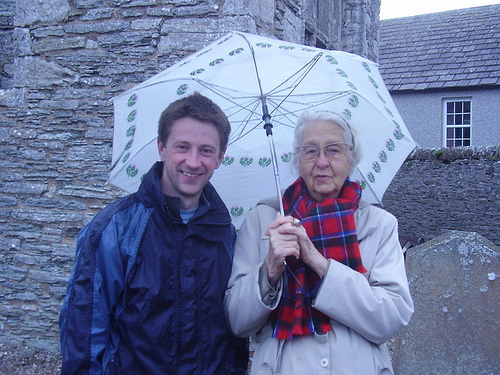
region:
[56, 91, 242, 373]
man under an umbrella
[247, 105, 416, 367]
woman under an umbrella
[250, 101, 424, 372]
woman next to man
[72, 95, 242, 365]
man next to woman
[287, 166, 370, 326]
scarf around woman's neck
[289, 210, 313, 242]
ring on woman's finger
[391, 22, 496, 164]
house in the background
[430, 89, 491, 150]
window on the house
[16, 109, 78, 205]
stones on a building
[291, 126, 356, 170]
glasses on the woman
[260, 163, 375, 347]
this is a red scarf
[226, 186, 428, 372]
this is a tan jacket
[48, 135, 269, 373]
this is a jacket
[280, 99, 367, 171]
this is white hair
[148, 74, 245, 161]
this is brown hair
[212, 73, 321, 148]
this is an umbrella frame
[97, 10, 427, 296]
this is an umbrella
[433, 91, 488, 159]
this is an window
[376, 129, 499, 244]
this is a wall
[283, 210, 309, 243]
this is a ring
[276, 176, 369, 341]
red plaid scarf around a woman's neck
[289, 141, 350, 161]
glasses over the woman's eyes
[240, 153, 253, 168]
green and pink floral print on a white umbrella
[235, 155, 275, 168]
two green and pink floral designs on a white umbrella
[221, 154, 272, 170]
three green and pink floral designs on a white umbrella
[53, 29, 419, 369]
two people under an umbrella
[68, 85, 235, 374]
man in a blue coat under an umbrella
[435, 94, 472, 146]
window on a building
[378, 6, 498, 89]
roof of a building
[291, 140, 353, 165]
metal framed retro glasses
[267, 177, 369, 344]
red, blue, black, and white plaid scarf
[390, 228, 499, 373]
cement stone headstone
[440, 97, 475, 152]
12 smaller paned window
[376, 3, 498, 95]
shingled roof of a house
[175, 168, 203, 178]
charming smile of a handsome young man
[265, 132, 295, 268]
metal pole of the umbrella metal pole to the umbrella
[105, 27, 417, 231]
white umbrella with granny and grandson underneath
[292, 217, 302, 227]
gaudy ring on granny's left hand ring finger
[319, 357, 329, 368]
tan button on an ecru coat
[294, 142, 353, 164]
metal framed eye glsses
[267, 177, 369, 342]
blue, red, and black plaid scarf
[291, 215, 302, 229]
big ol' gaudy metal ring on the granny's hand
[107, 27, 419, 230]
open white umbrella with little flower designs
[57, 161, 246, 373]
dark blue and light blue wind breaker jacket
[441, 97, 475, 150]
12 small paned white window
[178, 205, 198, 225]
powder blue t-shirt under the windbreaker jacket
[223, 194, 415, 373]
ecru colored cotton coat with hood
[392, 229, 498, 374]
medium size stone headstone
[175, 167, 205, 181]
nice, young man's smile